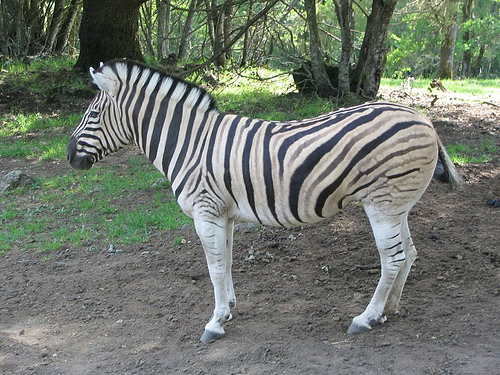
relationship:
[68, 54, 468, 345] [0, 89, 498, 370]
zebra in dirt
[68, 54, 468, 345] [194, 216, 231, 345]
zebra has leg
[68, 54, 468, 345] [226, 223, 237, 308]
zebra has leg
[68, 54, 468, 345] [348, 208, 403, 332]
zebra has leg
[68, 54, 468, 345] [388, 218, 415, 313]
zebra has leg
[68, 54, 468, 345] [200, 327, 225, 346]
zebra has hoof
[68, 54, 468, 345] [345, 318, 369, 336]
zebra has hoof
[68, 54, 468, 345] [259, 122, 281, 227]
zebra has stripe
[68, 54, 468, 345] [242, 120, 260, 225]
zebra has stripe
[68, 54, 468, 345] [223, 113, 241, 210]
zebra has stripe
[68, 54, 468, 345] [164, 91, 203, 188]
zebra has stripe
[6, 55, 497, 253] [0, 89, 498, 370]
grass on dirt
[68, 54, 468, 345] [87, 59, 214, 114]
zebra has mane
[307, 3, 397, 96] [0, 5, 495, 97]
tree in background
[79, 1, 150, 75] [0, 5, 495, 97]
tree in background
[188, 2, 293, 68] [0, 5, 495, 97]
tree in background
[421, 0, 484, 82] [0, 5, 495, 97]
tree in background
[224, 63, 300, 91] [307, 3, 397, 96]
sun through tree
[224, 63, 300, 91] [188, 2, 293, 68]
sun through tree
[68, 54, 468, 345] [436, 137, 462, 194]
zebra has tail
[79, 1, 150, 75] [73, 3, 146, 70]
tree has trunk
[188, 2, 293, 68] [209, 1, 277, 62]
tree has trunk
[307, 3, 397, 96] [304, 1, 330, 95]
tree has trunk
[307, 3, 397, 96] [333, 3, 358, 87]
tree has trunk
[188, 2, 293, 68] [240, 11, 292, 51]
tree has branches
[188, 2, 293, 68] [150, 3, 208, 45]
tree has branches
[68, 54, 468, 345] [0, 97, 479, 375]
zebra in shade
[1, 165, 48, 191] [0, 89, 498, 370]
rock in dirt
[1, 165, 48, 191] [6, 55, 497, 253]
rock in grass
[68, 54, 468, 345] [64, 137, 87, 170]
zebra has nose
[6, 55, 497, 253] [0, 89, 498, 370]
grass in dirt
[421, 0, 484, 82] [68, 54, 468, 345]
tree on right side of zebra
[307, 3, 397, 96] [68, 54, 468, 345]
tree on right side of zebra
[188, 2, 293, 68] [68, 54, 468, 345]
tree on right side of zebra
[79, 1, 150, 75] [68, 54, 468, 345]
tree on right side of zebra